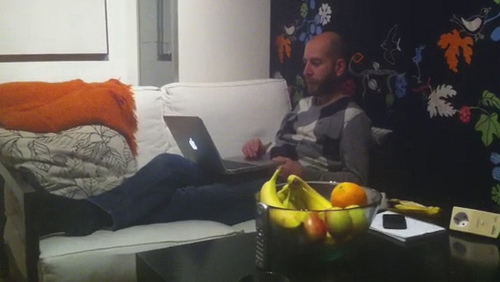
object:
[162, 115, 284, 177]
laptop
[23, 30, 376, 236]
man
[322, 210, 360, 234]
fruit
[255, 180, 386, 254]
bowl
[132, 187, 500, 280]
table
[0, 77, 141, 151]
blanket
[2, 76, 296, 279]
couch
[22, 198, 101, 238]
socks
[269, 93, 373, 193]
shirt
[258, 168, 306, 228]
banana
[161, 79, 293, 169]
pillow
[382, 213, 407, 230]
cellphone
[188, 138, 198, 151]
logo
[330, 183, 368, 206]
orange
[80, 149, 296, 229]
jeans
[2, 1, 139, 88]
wall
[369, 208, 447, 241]
notebook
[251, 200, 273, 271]
phone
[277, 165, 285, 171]
banana tip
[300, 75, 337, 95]
facial hair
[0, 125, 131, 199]
pillow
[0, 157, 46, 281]
arm rest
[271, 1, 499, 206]
floral design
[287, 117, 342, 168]
argyle design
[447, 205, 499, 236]
various items